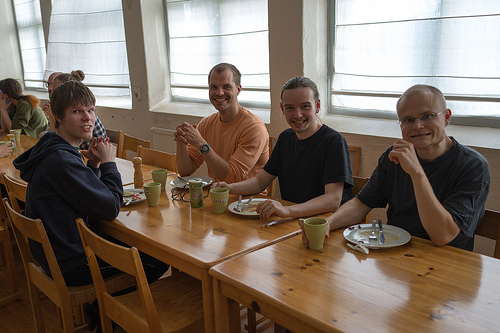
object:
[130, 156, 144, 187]
salt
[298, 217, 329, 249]
cup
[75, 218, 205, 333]
chair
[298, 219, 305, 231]
fingers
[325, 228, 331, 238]
fingers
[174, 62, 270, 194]
man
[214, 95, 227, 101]
smile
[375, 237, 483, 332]
shadow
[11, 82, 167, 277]
man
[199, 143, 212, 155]
watch.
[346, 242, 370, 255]
napkin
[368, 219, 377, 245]
fork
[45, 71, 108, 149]
woman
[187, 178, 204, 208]
shaker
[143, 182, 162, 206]
cup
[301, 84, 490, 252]
man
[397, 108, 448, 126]
glasses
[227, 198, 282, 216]
plate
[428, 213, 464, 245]
elbow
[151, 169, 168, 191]
cup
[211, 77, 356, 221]
man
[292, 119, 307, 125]
smiling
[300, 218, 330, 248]
hand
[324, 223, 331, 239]
thumb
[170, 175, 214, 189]
plate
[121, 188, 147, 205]
plate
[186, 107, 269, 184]
shirt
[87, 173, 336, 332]
table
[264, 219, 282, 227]
knife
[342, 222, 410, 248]
plate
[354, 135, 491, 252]
black shirt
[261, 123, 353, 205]
black shirt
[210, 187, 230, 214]
cup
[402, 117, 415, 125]
lens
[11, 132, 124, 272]
jacket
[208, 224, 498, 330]
table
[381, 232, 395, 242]
sauce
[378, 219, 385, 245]
knife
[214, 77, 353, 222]
woman